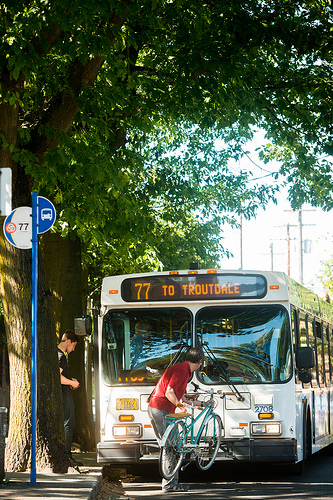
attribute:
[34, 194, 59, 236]
sign — blue, half circle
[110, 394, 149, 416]
license plate — yellow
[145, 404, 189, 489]
pants — grey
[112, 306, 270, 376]
bus windows — glass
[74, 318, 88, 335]
mirror — large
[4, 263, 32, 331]
tree trunk — large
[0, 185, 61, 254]
bus signs — pole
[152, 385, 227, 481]
bicycle — turqoise, white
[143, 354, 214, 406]
shirt — short sleeve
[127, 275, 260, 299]
sign — digital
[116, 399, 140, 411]
license plate — yellow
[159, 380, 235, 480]
bike — blue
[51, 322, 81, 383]
man — standing, looking down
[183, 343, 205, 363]
hair — short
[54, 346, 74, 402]
shirt — black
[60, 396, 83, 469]
pants — gray